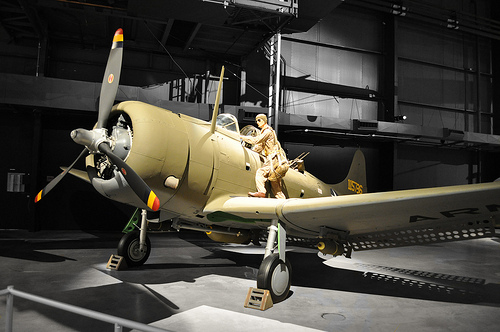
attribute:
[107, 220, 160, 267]
wheel — black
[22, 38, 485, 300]
plane — one, tan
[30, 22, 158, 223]
prop — black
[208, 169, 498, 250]
wing — one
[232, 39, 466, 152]
wall — gray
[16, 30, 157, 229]
propeller — red, yellow, black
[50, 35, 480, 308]
jet — fighter, old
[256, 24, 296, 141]
ladder — steel 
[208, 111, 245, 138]
windshield — plane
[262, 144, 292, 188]
bag — one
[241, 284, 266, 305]
blocks — wheel stop 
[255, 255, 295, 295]
wheel — under 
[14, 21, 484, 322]
airplane — old 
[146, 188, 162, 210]
stripes — red and yellow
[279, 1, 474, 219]
doors — two story garage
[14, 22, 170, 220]
propeller — black 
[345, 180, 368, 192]
numbers — yellow 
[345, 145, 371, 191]
fin — tail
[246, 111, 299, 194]
man — statue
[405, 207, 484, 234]
lettering — large black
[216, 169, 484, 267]
wing — bottom 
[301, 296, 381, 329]
floor — grey 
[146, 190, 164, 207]
stripe — red, black and yellow 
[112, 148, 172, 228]
propeller — tip 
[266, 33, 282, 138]
ladder — long silver 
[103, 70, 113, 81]
writing — yellow 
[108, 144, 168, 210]
fin — tail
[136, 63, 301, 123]
railing — grey , part  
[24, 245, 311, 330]
platform — high , bottom 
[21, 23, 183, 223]
propeller — airplane 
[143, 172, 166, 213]
stripes — red , yellow  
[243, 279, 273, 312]
wedge — wooden wheel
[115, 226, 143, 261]
wheel — landing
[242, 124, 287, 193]
uniform — pilot 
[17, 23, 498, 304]
plane — old fashioned beige, antique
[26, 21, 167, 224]
propeller — pointy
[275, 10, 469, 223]
garage doors — two story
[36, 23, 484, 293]
airplane — antique 